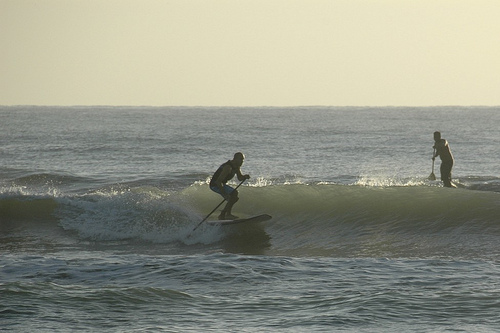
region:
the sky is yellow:
[202, 20, 372, 103]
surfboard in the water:
[213, 210, 273, 230]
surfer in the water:
[195, 145, 256, 214]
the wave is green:
[310, 194, 400, 244]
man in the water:
[419, 127, 459, 181]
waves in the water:
[74, 194, 155, 247]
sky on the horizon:
[12, 90, 154, 163]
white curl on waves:
[344, 167, 404, 189]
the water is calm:
[56, 108, 210, 140]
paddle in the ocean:
[194, 208, 219, 235]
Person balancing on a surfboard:
[182, 148, 279, 235]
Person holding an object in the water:
[423, 128, 462, 196]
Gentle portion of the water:
[0, 104, 497, 164]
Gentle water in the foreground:
[0, 247, 499, 332]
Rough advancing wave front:
[3, 175, 499, 254]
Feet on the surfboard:
[201, 209, 276, 232]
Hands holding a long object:
[173, 170, 252, 250]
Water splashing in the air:
[195, 164, 434, 187]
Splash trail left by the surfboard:
[58, 185, 236, 245]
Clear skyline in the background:
[1, 0, 498, 107]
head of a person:
[225, 144, 247, 161]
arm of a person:
[215, 165, 237, 184]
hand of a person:
[211, 185, 236, 192]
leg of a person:
[211, 193, 236, 205]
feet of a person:
[212, 210, 231, 219]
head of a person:
[430, 125, 442, 143]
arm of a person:
[427, 143, 442, 158]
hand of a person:
[431, 152, 437, 161]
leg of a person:
[437, 161, 459, 190]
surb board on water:
[202, 212, 292, 227]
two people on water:
[181, 125, 457, 230]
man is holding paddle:
[197, 164, 238, 229]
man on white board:
[199, 194, 263, 226]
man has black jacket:
[207, 159, 239, 191]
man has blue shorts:
[210, 171, 247, 208]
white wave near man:
[68, 181, 173, 241]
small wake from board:
[172, 173, 214, 250]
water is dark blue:
[217, 102, 336, 174]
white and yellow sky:
[222, 20, 345, 108]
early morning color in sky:
[293, 24, 425, 107]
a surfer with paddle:
[159, 126, 303, 278]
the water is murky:
[307, 199, 382, 251]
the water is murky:
[298, 189, 413, 259]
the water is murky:
[307, 219, 419, 278]